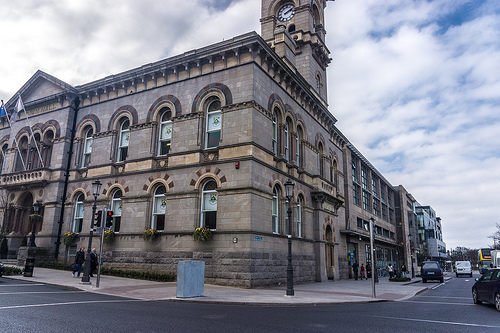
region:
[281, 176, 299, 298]
a tall lamp post on the sidewalk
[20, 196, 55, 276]
a tall lamp post on the sidewalk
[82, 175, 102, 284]
a tall lamp post on the sidewalk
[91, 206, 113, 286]
a traffic light post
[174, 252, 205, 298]
a metal box on the sidewalk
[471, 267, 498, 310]
a car driving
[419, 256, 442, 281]
a car parked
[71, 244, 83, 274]
a person walking on the sidewalk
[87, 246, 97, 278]
a person walking on the sidewalk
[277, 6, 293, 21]
a black and white clock face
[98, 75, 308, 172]
this is a building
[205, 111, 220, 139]
this is a window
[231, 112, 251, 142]
this is the wall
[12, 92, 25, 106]
this is a flag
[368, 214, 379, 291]
this is a pole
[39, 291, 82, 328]
this is a road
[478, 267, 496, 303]
this is a vehicle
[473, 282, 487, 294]
the vehicle is black in color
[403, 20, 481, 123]
these are the clouds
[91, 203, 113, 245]
this is a traffic light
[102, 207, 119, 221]
glowing red traffic light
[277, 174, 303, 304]
lamp on black post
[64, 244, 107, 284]
people walking on sidewalk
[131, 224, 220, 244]
plant on windows' edge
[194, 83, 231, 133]
arched top of window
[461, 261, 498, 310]
vehicle turning at intersection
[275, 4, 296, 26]
clock face on tower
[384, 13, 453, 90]
white clouds in daytime sky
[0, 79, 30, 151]
two flags on poles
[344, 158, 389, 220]
widows on upper floors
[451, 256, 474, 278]
back of a vehicle driving down the road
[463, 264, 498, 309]
car in mid-turn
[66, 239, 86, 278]
person walking along the sidewalk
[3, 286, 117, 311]
two white lines painted on the ground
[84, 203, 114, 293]
traffic light that is shining red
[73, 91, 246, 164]
row of four windows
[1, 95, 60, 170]
two flags hanging off the side of the building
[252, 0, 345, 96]
clock tower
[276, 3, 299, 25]
white and black clock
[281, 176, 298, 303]
black ligh post on the corner of the street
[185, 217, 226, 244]
flower boxes outside windows of a building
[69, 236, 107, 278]
two people walking on a sidewalk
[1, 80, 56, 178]
two flags and flag poles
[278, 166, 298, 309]
a black street lamp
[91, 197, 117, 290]
a traffic light showing red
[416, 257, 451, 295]
a blue car parked next to road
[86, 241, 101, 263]
a person with grey hair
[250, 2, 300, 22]
a clock in a clock tower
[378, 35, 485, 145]
white clouds in a blue sky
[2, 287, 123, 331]
white lines painted on a road